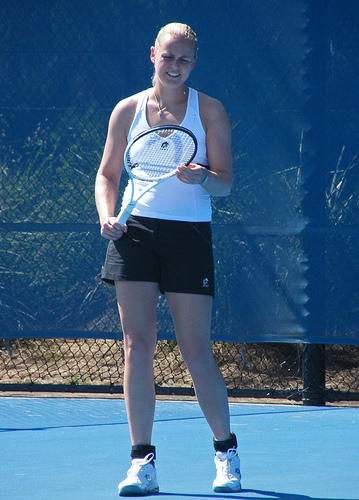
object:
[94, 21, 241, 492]
woman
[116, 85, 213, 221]
tank top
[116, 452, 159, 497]
tennis shoe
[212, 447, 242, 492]
tennis shoe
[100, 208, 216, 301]
shorts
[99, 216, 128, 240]
hand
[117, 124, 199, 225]
tennis racket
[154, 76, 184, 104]
neck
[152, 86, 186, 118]
necklace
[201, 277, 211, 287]
logo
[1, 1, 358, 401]
fence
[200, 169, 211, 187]
watch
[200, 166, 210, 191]
wrist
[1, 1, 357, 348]
netting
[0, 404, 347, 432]
shadow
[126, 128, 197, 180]
strings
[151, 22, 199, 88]
hair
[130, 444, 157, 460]
ankle weight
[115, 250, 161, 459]
leg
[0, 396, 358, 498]
tennis court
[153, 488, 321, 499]
shadow